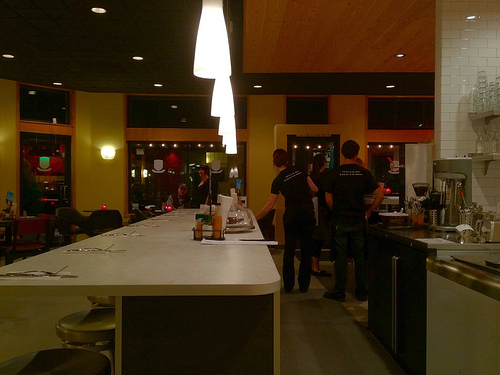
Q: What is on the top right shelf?
A: Glasses.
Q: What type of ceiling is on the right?
A: Wood.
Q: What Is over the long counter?
A: Light fixtures.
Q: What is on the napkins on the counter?
A: Utensils.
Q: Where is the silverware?
A: On the counter.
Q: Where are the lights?
A: Hanging over the bar.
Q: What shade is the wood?
A: Reddish.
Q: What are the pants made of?
A: Jeans.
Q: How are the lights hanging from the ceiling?
A: In a row.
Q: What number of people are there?
A: Two.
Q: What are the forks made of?
A: Silver.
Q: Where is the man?
A: In the kitchen.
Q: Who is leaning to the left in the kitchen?
A: The woman.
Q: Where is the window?
A: Inside the restaurant.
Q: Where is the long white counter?
A: In a restaurant.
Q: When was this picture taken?
A: At night.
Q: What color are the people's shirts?
A: Black.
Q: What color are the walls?
A: Yellow.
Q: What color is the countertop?
A: White.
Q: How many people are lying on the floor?
A: Zero.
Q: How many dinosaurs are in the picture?
A: Zero.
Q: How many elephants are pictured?
A: Zero.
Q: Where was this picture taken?
A: A restaurant.